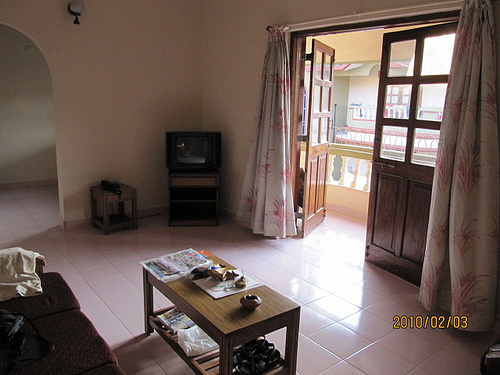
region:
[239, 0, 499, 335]
white and pink drapes on a window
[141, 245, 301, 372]
a wooden coffee table on a tile floor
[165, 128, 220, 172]
a black TV in a small entertainment unit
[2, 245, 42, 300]
a white cloth on the armrest of a couch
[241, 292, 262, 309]
an ashtray on a table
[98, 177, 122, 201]
a black phone on a small table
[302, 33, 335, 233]
an opened door to a balcony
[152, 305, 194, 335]
a newspaper on the shelf of a coffee table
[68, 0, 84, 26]
a light fixture on a wall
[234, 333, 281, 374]
a bunch of black wires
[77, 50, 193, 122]
the wall is dark in colour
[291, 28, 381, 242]
the door is open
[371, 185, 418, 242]
the door is brown in colour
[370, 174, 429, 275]
the door is wooden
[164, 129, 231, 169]
the television is on the corner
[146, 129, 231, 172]
the television is off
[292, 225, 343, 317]
the wall is tilled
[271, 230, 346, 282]
the tiles are white in colour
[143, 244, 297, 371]
the table is wooden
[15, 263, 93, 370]
the sofa is brown in colour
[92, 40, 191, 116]
this is the wall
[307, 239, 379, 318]
this is the floor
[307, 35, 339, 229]
this is the door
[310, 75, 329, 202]
the door is wooden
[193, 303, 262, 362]
this is a table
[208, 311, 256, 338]
the table is wooden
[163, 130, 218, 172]
this is a television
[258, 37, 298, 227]
this is a curtain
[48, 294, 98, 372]
this is a couch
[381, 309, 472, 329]
this is a writing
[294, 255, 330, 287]
A white tiled floor in the house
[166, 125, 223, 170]
A black television set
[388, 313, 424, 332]
Year that this picture was copyrighted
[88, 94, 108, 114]
Small part of the white wall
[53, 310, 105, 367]
Medium section of the couch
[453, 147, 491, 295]
Large patch of the curtains that cover the door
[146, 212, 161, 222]
Black cord that connects to an outlet plug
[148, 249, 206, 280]
Paper that is on the mini desk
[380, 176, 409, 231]
Small part of the wooden door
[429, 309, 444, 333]
Month the picture was copyrighted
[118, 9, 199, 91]
the walls are light pink in color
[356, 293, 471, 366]
the floor is brown in color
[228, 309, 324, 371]
the table is wooden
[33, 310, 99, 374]
the couch is brown in color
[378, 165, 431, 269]
the door is wooden and brown in color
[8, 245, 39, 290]
cloth is white in color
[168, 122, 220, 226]
the cupboard is wooden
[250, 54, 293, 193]
the curtains are multicoloured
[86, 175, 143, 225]
the stool is brown in color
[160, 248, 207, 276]
the magazine is white in color